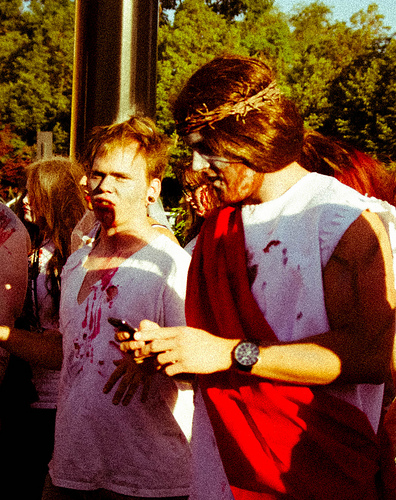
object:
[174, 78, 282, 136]
headband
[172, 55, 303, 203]
head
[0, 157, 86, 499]
person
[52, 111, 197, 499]
person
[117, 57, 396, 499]
person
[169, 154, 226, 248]
person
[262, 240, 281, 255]
red spot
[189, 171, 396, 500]
fabric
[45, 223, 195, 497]
shirt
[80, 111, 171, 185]
hair neat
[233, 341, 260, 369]
clock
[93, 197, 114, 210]
mouth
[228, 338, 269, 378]
wrist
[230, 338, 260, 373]
watch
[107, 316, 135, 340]
phone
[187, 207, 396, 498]
sash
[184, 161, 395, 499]
body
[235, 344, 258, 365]
face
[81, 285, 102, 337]
stains